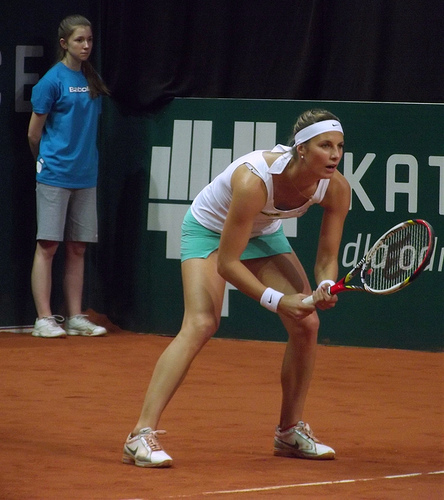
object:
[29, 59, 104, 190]
shirt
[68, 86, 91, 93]
word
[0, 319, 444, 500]
court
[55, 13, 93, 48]
hair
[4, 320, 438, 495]
ground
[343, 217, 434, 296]
racket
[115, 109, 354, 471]
woman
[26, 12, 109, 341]
girl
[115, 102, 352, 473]
tennis player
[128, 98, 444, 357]
advertising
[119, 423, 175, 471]
shoe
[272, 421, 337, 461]
shoe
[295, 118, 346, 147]
headband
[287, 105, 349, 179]
head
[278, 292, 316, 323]
hands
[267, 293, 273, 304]
nike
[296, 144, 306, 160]
ear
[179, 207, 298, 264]
skirt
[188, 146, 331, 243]
tank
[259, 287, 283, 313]
wrist band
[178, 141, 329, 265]
tennis uniform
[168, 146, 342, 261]
body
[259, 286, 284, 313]
band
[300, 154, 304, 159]
earring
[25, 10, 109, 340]
woman